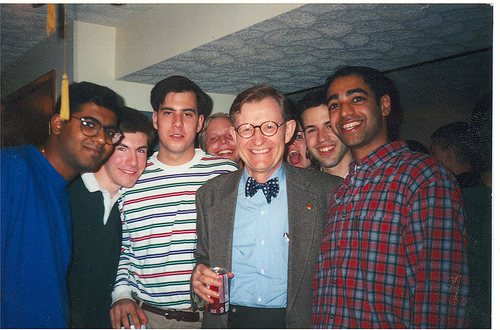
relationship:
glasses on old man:
[233, 120, 287, 136] [196, 86, 346, 327]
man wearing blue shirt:
[2, 80, 125, 327] [1, 145, 74, 329]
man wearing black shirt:
[68, 105, 155, 327] [67, 172, 123, 326]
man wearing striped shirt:
[111, 75, 240, 328] [113, 150, 240, 307]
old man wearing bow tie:
[196, 86, 346, 327] [245, 176, 280, 201]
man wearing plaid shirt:
[312, 65, 466, 326] [311, 138, 471, 329]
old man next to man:
[196, 86, 346, 327] [312, 65, 466, 326]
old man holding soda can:
[196, 86, 346, 327] [206, 265, 231, 314]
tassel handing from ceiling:
[60, 74, 70, 119] [3, 2, 494, 94]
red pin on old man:
[307, 204, 312, 208] [196, 86, 346, 327]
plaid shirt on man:
[311, 138, 471, 329] [312, 65, 466, 326]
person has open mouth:
[288, 118, 320, 169] [290, 151, 301, 164]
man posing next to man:
[2, 80, 125, 327] [68, 105, 155, 327]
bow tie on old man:
[245, 176, 280, 201] [196, 86, 346, 327]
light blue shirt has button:
[230, 164, 288, 308] [260, 270, 264, 274]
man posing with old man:
[312, 65, 466, 326] [196, 86, 346, 327]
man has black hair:
[2, 80, 125, 327] [57, 81, 122, 119]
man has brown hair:
[68, 105, 155, 327] [120, 105, 155, 147]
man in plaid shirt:
[312, 65, 466, 326] [311, 138, 471, 329]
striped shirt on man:
[113, 150, 240, 307] [111, 75, 240, 328]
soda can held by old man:
[206, 265, 231, 314] [196, 86, 346, 327]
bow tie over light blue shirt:
[245, 176, 280, 201] [230, 164, 288, 308]